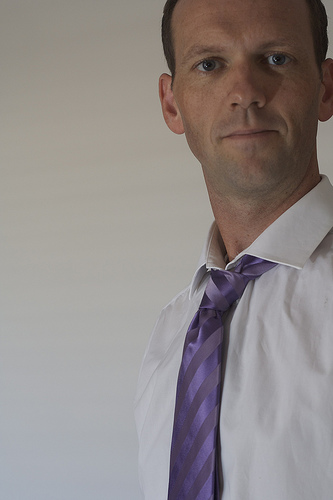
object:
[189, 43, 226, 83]
eye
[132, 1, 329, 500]
man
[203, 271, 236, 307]
knot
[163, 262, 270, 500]
tie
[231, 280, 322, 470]
shirt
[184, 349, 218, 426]
pattern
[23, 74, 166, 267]
wall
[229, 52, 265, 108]
nose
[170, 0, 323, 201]
face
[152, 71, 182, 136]
ear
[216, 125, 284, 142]
mouth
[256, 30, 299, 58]
eyebrow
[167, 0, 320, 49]
forehead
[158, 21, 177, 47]
hair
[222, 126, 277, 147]
lip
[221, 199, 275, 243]
skin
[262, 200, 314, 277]
collar